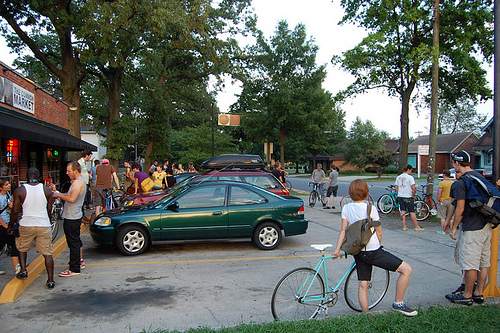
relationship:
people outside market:
[38, 139, 150, 280] [0, 65, 95, 208]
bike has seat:
[257, 214, 410, 332] [309, 231, 338, 260]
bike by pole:
[257, 214, 410, 332] [425, 127, 436, 211]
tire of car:
[252, 213, 295, 257] [99, 185, 310, 256]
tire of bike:
[258, 241, 324, 330] [257, 214, 410, 332]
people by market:
[38, 139, 150, 280] [0, 65, 95, 208]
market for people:
[0, 65, 95, 208] [38, 139, 150, 280]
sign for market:
[200, 92, 249, 155] [0, 65, 95, 208]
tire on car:
[252, 213, 295, 257] [99, 185, 310, 256]